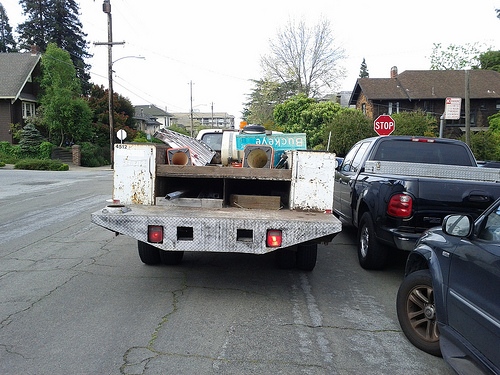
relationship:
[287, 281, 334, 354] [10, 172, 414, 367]
lines on street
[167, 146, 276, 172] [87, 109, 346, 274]
cones on truck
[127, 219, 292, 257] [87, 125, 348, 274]
tail lights on truck